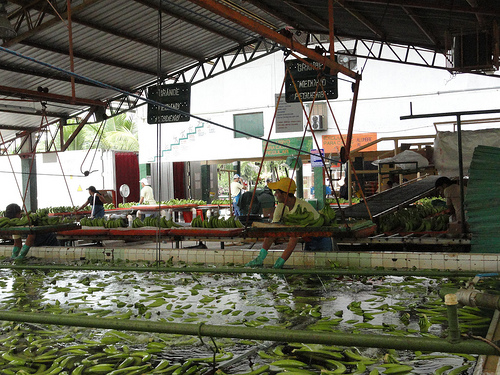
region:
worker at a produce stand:
[243, 175, 328, 273]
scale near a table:
[116, 182, 133, 201]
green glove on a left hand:
[271, 253, 285, 270]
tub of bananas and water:
[2, 257, 486, 374]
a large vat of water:
[3, 258, 495, 374]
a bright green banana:
[151, 357, 168, 371]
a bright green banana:
[157, 361, 181, 373]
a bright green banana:
[117, 355, 132, 367]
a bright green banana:
[105, 352, 130, 359]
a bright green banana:
[86, 362, 114, 373]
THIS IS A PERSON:
[267, 181, 318, 253]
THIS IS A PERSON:
[247, 187, 268, 213]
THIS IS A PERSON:
[85, 183, 101, 220]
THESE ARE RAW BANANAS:
[40, 329, 92, 360]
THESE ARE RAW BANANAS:
[335, 304, 425, 332]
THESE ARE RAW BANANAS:
[281, 347, 350, 370]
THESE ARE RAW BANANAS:
[79, 221, 125, 232]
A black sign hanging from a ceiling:
[145, 85, 190, 122]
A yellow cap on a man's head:
[262, 176, 297, 191]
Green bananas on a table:
[189, 213, 242, 229]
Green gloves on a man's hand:
[249, 248, 283, 270]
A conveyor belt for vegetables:
[346, 173, 448, 220]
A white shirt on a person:
[274, 197, 317, 225]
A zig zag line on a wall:
[157, 120, 202, 160]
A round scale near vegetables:
[118, 183, 130, 197]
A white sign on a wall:
[272, 93, 301, 133]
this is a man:
[223, 160, 351, 286]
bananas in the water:
[19, 234, 486, 371]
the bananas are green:
[36, 235, 443, 374]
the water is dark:
[11, 232, 476, 373]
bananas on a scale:
[219, 3, 417, 291]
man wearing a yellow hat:
[252, 154, 308, 202]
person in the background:
[48, 168, 144, 235]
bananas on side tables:
[13, 168, 213, 237]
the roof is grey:
[2, 0, 494, 151]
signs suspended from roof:
[114, 40, 377, 140]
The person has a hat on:
[265, 175, 305, 212]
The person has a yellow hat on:
[263, 168, 299, 210]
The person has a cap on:
[261, 175, 303, 210]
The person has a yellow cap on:
[264, 174, 301, 211]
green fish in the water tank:
[124, 346, 152, 361]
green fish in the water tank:
[265, 352, 307, 367]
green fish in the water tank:
[305, 346, 341, 356]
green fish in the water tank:
[320, 355, 347, 370]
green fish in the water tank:
[50, 340, 91, 350]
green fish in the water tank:
[385, 300, 410, 310]